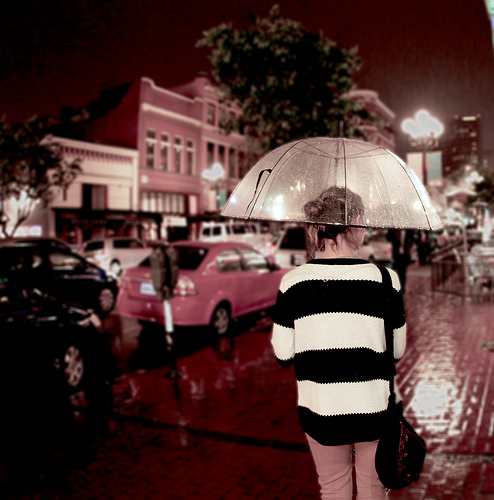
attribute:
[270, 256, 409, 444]
sweater — white, striped, black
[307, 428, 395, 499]
pants — beige, pink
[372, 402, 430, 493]
purse — black, brown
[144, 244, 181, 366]
meter — black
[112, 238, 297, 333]
car — pink, red, parked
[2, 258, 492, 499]
sidewalk — red, wet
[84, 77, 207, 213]
building — red, brick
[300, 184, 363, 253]
hair — brown, dark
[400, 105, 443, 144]
lights — wet, bright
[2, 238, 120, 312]
van — black, driving, grey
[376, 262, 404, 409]
strap — long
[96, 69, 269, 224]
buildings — pink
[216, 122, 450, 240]
umbrella — transparent, clear, see through